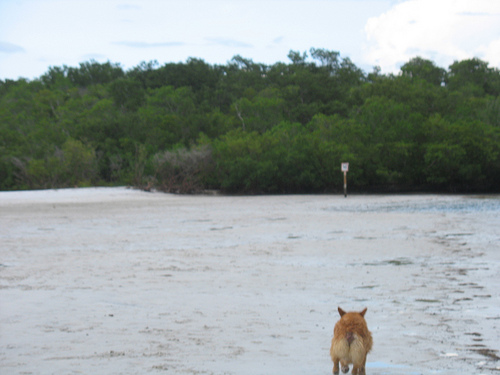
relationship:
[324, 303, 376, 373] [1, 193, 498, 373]
dog in water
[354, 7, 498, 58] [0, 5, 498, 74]
clouds in sky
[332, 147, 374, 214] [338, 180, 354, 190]
sign on a post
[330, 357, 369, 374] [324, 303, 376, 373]
legs on dog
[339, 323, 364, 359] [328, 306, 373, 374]
fur on a animal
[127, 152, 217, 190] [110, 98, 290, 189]
limbs on bushes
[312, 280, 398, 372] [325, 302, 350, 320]
dog has ears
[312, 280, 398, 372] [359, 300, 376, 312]
dog has ears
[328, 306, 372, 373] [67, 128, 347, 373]
fox on beach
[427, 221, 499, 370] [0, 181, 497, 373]
footprints in sand